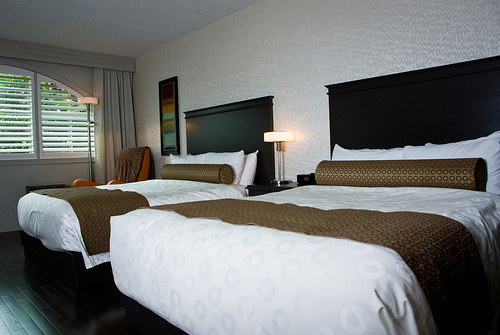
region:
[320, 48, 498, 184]
A black wooden headboard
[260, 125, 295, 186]
a lit up table lamp on a nightstand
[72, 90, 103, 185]
powered on floor lamp next to the chair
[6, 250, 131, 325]
Brown hardwood floor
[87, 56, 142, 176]
Brown curtains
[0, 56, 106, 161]
Arched window, with open slats and white trim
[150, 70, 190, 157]
colorful painting haning on wall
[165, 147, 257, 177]
White pillows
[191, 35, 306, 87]
patterned, ivory colored wall paper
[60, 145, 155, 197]
Orange chair in the corner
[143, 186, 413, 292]
Brown blanket on a bed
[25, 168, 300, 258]
White blanket on a bed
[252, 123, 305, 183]
Lamp on a stand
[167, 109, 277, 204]
Black headboard on a bed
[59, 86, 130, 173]
Silver floor lamp by a window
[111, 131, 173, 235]
Orange chair in a corner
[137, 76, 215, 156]
Picture on a wall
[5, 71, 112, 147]
Blinds in a window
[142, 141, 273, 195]
Pillows on a bed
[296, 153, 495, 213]
Brown roll on a bed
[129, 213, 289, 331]
a white bed spread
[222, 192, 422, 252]
a brown tapestry on a bed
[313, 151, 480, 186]
a brown roll type pillow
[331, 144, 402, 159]
white pillow case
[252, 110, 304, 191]
a lamp beside the bed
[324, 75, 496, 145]
a black wooden head board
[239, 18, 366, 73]
white wall paper with a design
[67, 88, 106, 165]
a lamp beside the window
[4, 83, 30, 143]
white blinds in the window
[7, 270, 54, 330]
a dark colored wood floor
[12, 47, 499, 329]
two beds with white bedspreads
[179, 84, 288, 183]
a black headboard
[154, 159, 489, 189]
two long, round brown pillows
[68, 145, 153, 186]
an orange chair covered with a brown blanket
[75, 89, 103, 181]
a tall floor lamp by the window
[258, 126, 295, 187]
a short lamp on the nightstand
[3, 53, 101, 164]
a window with open blinds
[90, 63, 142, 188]
a white curtain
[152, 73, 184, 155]
a picture with a striped pattern on the wall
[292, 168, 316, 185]
an alarm clock on the nightstand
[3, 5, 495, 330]
Room of a hotel.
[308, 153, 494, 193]
Brown pillow on bed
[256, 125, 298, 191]
Lamp in center on night table.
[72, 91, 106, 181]
Floor lamp next to the window.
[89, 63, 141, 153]
Curtain is beige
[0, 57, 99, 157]
Window has arch form.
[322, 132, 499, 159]
White pillows behind brown pillow.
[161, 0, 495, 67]
Wall of room is white.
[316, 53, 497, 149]
Headboard of bed is dark brown.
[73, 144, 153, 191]
Chair in corner is orange.